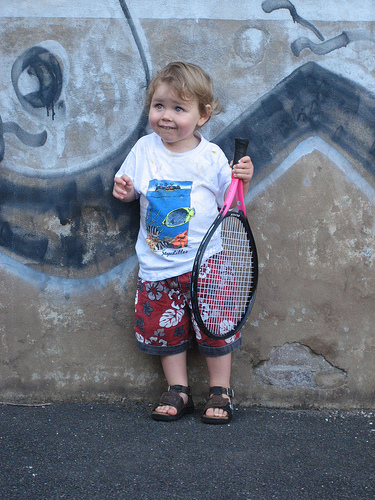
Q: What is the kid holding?
A: Racket.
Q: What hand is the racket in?
A: Left.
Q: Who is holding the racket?
A: The kid.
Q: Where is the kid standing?
A: Front of the wall.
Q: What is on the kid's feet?
A: Sandals.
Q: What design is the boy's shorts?
A: Flower.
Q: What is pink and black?
A: Tennis racket.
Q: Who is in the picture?
A: A child.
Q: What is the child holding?
A: A racquet.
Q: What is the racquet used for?
A: To play tennis.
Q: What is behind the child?
A: A wall.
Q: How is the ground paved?
A: With asphalt.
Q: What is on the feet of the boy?
A: Sandals.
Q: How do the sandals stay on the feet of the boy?
A: With buckles and straps.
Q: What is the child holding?
A: A tennis racket.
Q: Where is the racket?
A: In the child's hand.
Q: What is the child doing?
A: Standing.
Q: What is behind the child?
A: A wall.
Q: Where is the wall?
A: Behind the child.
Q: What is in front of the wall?
A: A child.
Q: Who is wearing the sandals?
A: The child.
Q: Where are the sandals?
A: On the child's feet.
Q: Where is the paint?
A: On the wall.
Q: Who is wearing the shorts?
A: The child.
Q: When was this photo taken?
A: Daytime.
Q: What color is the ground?
A: Black.